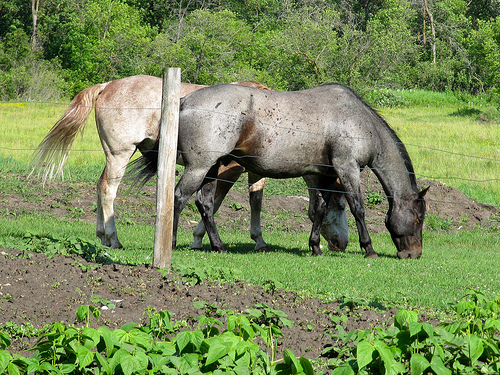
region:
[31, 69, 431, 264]
the two horses grazing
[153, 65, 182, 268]
the wooden post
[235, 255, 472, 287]
the grass on the ground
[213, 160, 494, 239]
the dirt mound behind the surveys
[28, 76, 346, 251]
the light colored horse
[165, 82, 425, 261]
the darker colored horse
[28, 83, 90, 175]
the tail on the lighter colored horse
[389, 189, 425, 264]
the head of the darker horse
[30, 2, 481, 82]
the trees behind the horses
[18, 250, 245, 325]
the dirt near the wooden post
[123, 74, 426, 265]
gray horse grazing in green grassy field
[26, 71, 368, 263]
white and gray horse grazing next to gray horse in grassy green field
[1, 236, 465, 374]
patch of black soil near fence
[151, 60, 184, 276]
light gray and brown fence post near horses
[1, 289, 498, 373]
small green leafy plants near fence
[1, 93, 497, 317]
green grassy field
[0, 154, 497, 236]
patch of black dirt in the middle of a green grassy field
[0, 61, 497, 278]
wire metal fence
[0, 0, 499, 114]
large row of trees next to green grassy field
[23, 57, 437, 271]
two horses grazing in a grassy field near a fence post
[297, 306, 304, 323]
the soil is black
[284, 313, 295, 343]
the soil is black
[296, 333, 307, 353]
the soil is black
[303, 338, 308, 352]
the soil is black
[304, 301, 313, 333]
the soil is black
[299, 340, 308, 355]
the soil is black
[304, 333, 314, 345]
the soil is black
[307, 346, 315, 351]
the soil is black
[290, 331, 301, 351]
the soil is black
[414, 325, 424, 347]
the leaves are green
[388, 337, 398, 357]
the leaves are green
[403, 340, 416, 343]
the leaves are green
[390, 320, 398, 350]
the leaves are green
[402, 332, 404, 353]
the leaves are green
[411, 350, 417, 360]
the leaves are green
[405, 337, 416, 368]
the leaves are green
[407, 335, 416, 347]
the leaves are green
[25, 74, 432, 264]
two horses grazing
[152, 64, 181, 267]
wooden fence post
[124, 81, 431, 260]
gray spotted horse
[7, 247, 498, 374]
garden area with tilled dirt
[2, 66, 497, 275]
wire fence keeping horses out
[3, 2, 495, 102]
lots of green trees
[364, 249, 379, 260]
a front horse hoof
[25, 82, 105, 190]
a horse tail for swatting flies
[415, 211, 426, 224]
horse eye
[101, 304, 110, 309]
white rock in the garden